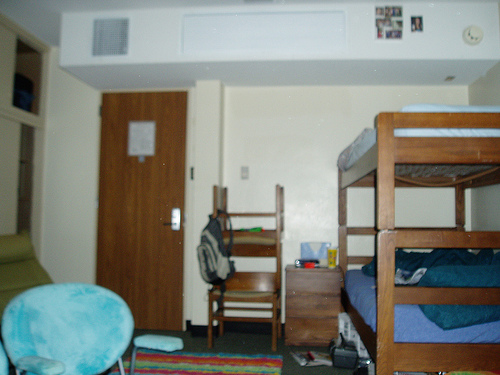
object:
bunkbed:
[324, 96, 498, 375]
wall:
[466, 61, 499, 258]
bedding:
[340, 98, 494, 172]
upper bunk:
[321, 98, 499, 205]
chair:
[204, 178, 294, 266]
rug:
[108, 348, 284, 375]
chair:
[3, 275, 142, 374]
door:
[89, 88, 191, 333]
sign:
[125, 120, 157, 162]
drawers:
[281, 291, 343, 322]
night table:
[283, 262, 342, 353]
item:
[322, 242, 343, 272]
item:
[299, 261, 321, 270]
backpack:
[195, 203, 239, 316]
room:
[0, 1, 496, 370]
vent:
[87, 13, 132, 56]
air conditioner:
[89, 16, 130, 56]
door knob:
[155, 204, 184, 235]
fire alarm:
[459, 22, 488, 51]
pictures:
[407, 16, 425, 34]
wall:
[56, 0, 499, 88]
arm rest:
[101, 306, 141, 364]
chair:
[0, 230, 58, 325]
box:
[325, 325, 367, 370]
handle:
[335, 328, 350, 349]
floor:
[103, 327, 361, 374]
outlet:
[239, 164, 250, 182]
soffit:
[55, 10, 203, 90]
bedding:
[343, 260, 498, 341]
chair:
[205, 233, 283, 349]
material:
[0, 280, 138, 374]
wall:
[41, 45, 474, 336]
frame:
[332, 105, 499, 373]